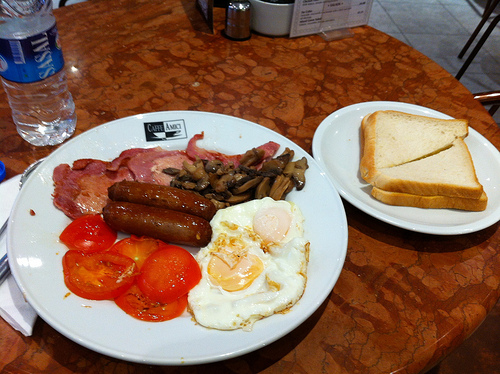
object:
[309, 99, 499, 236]
food plate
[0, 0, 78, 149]
bottle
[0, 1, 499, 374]
table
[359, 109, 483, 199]
bread slices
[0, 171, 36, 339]
napkin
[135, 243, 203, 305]
tomato slices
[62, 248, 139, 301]
tomato slices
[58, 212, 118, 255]
tomato slices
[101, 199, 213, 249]
cooked sausages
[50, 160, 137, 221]
meat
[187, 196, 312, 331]
egg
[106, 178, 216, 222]
sausage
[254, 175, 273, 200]
mushrooms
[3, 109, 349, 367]
plate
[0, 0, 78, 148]
water